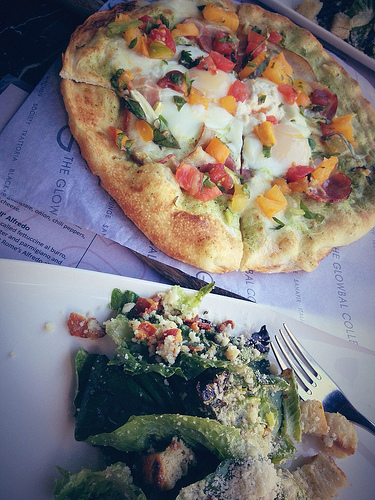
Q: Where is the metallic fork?
A: On the edge of the salad plate.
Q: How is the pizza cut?
A: Into four slices.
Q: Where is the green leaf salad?
A: On the table.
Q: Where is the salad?
A: On a white plate.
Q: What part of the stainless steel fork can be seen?
A: The top.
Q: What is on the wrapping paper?
A: A pizza.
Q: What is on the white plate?
A: A salad.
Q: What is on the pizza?
A: Cheese and vegetables.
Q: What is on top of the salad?
A: Parmesan cheese.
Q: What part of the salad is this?
A: A piece of lettuce.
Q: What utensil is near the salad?
A: A fork.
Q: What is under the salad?
A: A white plate.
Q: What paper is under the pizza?
A: A menu.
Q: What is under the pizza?
A: A white paper.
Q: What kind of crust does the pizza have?
A: Golden yellow.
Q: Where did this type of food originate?
A: Italy.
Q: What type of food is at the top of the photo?
A: Pizza.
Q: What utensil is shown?
A: Fork.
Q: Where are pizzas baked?
A: Oven.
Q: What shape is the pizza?
A: Circle.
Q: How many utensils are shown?
A: One.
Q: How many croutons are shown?
A: Four.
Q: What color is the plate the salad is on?
A: White.